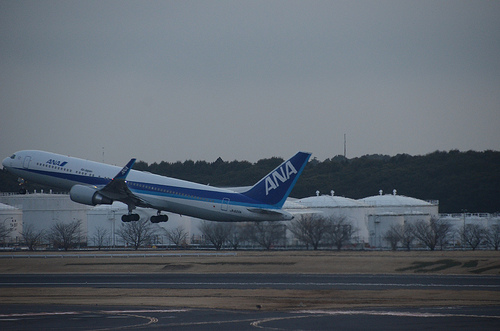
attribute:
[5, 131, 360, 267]
airplane — tail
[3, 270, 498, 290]
runway — dark, gray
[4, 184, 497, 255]
buildings — white, domed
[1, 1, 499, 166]
sky — blue, white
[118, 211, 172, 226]
wheels — black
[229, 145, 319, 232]
tail — blue, white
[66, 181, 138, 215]
engines — white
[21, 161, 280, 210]
stripe — blue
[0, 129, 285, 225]
plane — taking off